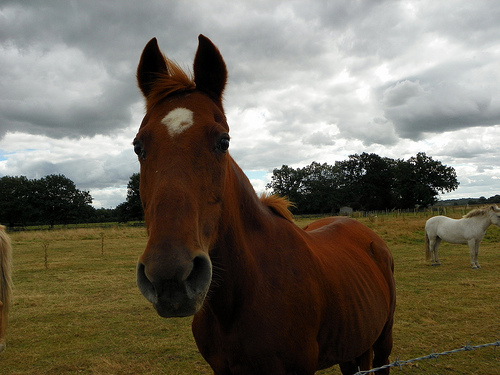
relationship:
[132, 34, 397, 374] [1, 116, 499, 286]
horse in background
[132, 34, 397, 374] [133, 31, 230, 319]
horse has head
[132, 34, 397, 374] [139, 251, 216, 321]
horse has nose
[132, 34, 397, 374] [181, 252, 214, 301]
horse has nostril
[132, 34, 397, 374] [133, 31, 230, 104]
horse has ears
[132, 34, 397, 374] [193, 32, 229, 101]
horse has ear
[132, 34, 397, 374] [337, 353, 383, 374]
horse has legs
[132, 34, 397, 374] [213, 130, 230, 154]
horse has eye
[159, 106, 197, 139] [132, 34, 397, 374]
spot on horse